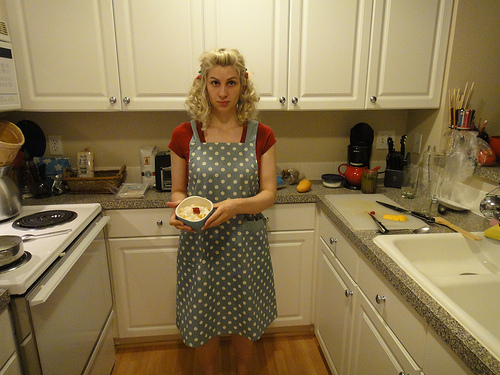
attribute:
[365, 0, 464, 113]
cabinet — white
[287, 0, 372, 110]
cabinet — white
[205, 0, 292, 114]
cabinet — white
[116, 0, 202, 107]
cabinet — white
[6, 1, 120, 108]
cabinet — white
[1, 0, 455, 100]
cabinets — white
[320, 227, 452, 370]
drawers — white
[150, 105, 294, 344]
dress — grey, white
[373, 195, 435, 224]
knife — large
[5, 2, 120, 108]
cabinets — white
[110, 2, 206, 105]
cabinets — white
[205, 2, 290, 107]
cabinets — white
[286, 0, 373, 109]
cabinets — white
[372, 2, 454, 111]
cabinets — white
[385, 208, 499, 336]
sink — white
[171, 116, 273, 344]
apron — polka dotted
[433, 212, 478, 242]
spoon — wooden, brown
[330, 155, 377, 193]
tea kettle — red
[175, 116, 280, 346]
dress — polka dot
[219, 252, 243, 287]
dots — white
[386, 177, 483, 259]
counter — grey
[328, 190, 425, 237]
cutting board — white, large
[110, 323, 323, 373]
floor — wooden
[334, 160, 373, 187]
tea pot — Red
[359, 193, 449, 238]
knife — large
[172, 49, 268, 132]
hair — blonde